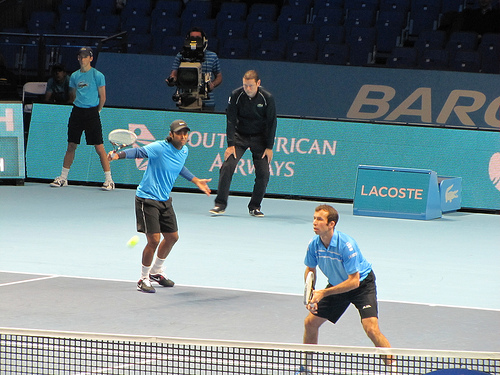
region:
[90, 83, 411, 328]
two people playing tennis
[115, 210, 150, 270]
ball in the air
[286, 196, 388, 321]
man with a racket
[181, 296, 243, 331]
court below the players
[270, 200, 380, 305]
man with a blue shirt on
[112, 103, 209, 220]
man with a hat on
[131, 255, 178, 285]
socks on the man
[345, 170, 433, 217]
word in the background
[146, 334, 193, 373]
net in front of the players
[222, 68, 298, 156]
person wearing black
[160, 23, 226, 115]
The man is operating a camera.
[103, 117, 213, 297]
Man's arms are outstretched.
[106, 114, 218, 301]
The man is holding a tennis racket.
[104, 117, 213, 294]
The man is wearing a cap.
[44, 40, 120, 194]
The man is standing with legs apart.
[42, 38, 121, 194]
The man's arms are behind his back.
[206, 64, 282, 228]
The man is slightly crouched.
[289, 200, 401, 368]
The man is holding a tennis racket.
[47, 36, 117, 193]
The man is wearing a cap.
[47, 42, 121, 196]
The man is wearing black shorts.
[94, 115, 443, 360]
two guys playing tennis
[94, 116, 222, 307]
guy swinging his racquet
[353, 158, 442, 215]
blue and white sign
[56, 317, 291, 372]
black net with white trim on top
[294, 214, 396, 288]
blue and white shirt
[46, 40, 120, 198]
guy wearing blue shirt and black shorts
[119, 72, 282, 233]
referee standing behind tennis player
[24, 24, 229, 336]
guy behind camera facing court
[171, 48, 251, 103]
person wearing blue striped shirt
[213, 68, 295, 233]
guy wearing black pants and top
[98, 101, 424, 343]
Two tennis players on a tennis court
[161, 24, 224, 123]
A cameraman behind a big camera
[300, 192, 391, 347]
A man in a blue collared shirt with white stripes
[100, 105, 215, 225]
A man in a blue shirt with different blue sleeves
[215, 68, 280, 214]
A man in a black long sleeve shirt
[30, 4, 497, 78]
Empty seats in the stands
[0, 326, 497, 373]
A tennis net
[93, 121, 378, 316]
Two tennis rackets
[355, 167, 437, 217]
A sponsor's sign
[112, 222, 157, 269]
A yellow tennis ball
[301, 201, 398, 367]
man with blue uniform bending over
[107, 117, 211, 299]
man with blue uniform with white racket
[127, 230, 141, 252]
small green tennis ball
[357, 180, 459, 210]
lacoste white letters and white symbol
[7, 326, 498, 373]
black large tennis ned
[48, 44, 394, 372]
three mans with blue t-shirts and black pants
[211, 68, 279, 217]
man with black suit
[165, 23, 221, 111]
cameraman with blue t-shirt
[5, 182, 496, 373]
blue and gray floor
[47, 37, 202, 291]
two man with blue uniform with black cap